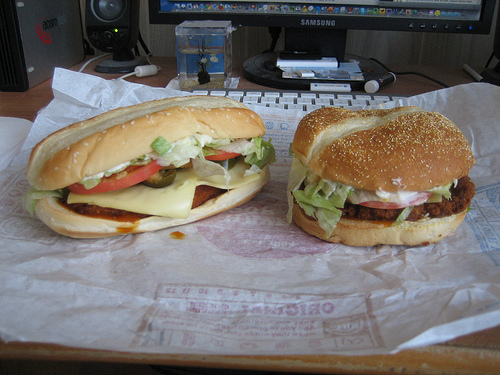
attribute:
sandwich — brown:
[26, 110, 293, 211]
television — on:
[143, 0, 498, 92]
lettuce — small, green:
[244, 82, 285, 114]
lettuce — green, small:
[277, 142, 354, 228]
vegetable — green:
[286, 165, 351, 240]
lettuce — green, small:
[297, 175, 348, 232]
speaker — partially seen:
[79, 5, 148, 77]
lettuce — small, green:
[303, 182, 332, 200]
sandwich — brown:
[283, 102, 474, 252]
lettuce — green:
[150, 135, 170, 156]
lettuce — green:
[244, 136, 264, 159]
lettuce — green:
[79, 175, 101, 189]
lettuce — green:
[21, 188, 64, 215]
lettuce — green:
[243, 154, 275, 166]